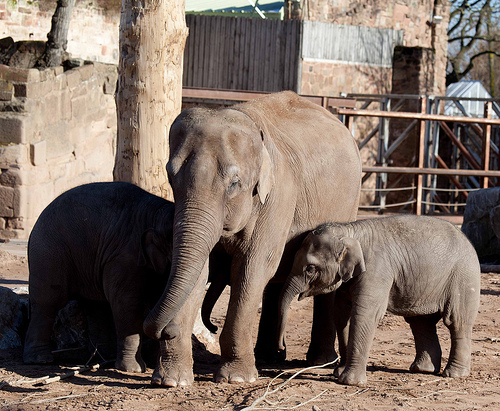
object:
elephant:
[273, 213, 493, 390]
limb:
[217, 348, 360, 411]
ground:
[0, 244, 498, 410]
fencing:
[334, 79, 500, 222]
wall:
[296, 1, 451, 207]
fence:
[181, 13, 301, 101]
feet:
[330, 362, 373, 389]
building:
[440, 71, 500, 214]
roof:
[440, 74, 500, 122]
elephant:
[143, 88, 364, 388]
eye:
[305, 264, 316, 274]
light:
[432, 15, 448, 30]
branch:
[6, 358, 116, 396]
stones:
[397, 394, 412, 407]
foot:
[149, 363, 194, 392]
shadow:
[0, 181, 294, 400]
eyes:
[221, 171, 250, 195]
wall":
[3, 39, 123, 243]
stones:
[1, 37, 62, 68]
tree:
[112, 0, 189, 206]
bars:
[179, 86, 355, 110]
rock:
[458, 181, 500, 273]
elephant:
[18, 179, 230, 375]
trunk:
[141, 199, 238, 342]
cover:
[301, 14, 403, 72]